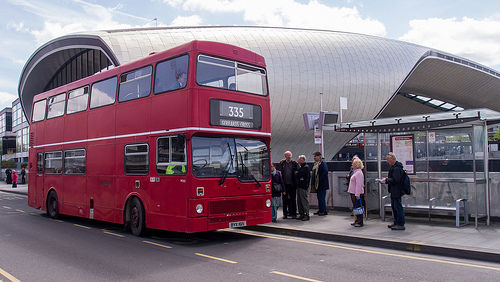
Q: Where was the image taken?
A: It was taken at the road.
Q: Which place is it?
A: It is a road.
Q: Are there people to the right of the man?
A: No, the person is to the left of the man.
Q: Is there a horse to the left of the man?
A: No, there is a person to the left of the man.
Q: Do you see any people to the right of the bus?
A: Yes, there is a person to the right of the bus.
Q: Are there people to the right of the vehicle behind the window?
A: Yes, there is a person to the right of the bus.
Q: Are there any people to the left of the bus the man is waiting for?
A: No, the person is to the right of the bus.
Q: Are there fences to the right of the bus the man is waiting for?
A: No, there is a person to the right of the bus.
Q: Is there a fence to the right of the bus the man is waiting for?
A: No, there is a person to the right of the bus.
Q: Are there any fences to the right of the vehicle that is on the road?
A: No, there is a person to the right of the bus.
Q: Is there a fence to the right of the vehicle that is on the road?
A: No, there is a person to the right of the bus.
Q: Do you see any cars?
A: No, there are no cars.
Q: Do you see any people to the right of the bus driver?
A: Yes, there is a person to the right of the bus driver.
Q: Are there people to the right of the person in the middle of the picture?
A: Yes, there is a person to the right of the bus driver.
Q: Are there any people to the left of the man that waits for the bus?
A: Yes, there is a person to the left of the man.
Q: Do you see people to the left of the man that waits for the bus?
A: Yes, there is a person to the left of the man.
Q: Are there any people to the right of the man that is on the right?
A: No, the person is to the left of the man.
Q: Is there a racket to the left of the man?
A: No, there is a person to the left of the man.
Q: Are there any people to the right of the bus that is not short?
A: Yes, there is a person to the right of the bus.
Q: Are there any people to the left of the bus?
A: No, the person is to the right of the bus.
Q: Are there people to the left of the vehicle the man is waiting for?
A: No, the person is to the right of the bus.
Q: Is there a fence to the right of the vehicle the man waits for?
A: No, there is a person to the right of the bus.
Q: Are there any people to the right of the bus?
A: Yes, there is a person to the right of the bus.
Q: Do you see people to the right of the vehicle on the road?
A: Yes, there is a person to the right of the bus.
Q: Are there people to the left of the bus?
A: No, the person is to the right of the bus.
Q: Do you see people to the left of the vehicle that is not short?
A: No, the person is to the right of the bus.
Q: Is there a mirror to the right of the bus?
A: No, there is a person to the right of the bus.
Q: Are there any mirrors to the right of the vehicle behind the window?
A: No, there is a person to the right of the bus.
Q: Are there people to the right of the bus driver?
A: Yes, there is a person to the right of the bus driver.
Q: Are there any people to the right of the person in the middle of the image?
A: Yes, there is a person to the right of the bus driver.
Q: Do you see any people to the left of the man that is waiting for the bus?
A: Yes, there is a person to the left of the man.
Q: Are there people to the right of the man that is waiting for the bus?
A: No, the person is to the left of the man.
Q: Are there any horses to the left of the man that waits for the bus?
A: No, there is a person to the left of the man.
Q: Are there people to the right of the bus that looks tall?
A: Yes, there is a person to the right of the bus.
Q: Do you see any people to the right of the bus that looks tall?
A: Yes, there is a person to the right of the bus.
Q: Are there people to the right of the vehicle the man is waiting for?
A: Yes, there is a person to the right of the bus.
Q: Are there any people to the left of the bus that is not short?
A: No, the person is to the right of the bus.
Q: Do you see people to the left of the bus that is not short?
A: No, the person is to the right of the bus.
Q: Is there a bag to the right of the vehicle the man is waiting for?
A: No, there is a person to the right of the bus.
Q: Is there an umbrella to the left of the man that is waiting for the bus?
A: No, there is a person to the left of the man.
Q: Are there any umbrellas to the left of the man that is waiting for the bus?
A: No, there is a person to the left of the man.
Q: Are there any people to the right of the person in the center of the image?
A: Yes, there is a person to the right of the bus driver.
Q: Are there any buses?
A: Yes, there is a bus.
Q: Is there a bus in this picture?
A: Yes, there is a bus.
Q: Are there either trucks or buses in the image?
A: Yes, there is a bus.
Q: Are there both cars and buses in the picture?
A: No, there is a bus but no cars.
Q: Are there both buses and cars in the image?
A: No, there is a bus but no cars.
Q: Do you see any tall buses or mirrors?
A: Yes, there is a tall bus.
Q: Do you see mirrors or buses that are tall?
A: Yes, the bus is tall.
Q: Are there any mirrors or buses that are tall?
A: Yes, the bus is tall.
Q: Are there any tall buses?
A: Yes, there is a tall bus.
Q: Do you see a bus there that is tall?
A: Yes, there is a bus that is tall.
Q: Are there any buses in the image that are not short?
A: Yes, there is a tall bus.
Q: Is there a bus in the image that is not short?
A: Yes, there is a tall bus.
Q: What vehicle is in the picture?
A: The vehicle is a bus.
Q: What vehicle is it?
A: The vehicle is a bus.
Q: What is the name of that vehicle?
A: That is a bus.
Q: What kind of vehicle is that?
A: That is a bus.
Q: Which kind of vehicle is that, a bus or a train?
A: That is a bus.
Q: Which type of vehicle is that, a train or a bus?
A: That is a bus.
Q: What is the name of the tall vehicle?
A: The vehicle is a bus.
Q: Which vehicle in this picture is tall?
A: The vehicle is a bus.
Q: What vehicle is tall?
A: The vehicle is a bus.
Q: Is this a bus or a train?
A: This is a bus.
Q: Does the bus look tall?
A: Yes, the bus is tall.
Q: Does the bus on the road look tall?
A: Yes, the bus is tall.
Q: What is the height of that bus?
A: The bus is tall.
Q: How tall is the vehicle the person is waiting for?
A: The bus is tall.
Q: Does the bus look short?
A: No, the bus is tall.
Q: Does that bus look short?
A: No, the bus is tall.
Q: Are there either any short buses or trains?
A: No, there is a bus but it is tall.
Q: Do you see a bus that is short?
A: No, there is a bus but it is tall.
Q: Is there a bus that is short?
A: No, there is a bus but it is tall.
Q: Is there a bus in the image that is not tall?
A: No, there is a bus but it is tall.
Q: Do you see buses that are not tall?
A: No, there is a bus but it is tall.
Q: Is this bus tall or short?
A: The bus is tall.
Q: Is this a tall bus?
A: Yes, this is a tall bus.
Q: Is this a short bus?
A: No, this is a tall bus.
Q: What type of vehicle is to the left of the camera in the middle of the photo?
A: The vehicle is a bus.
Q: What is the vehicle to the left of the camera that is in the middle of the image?
A: The vehicle is a bus.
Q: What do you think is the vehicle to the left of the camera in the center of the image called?
A: The vehicle is a bus.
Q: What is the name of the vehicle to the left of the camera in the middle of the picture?
A: The vehicle is a bus.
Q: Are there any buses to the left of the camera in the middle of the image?
A: Yes, there is a bus to the left of the camera.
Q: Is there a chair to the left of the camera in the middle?
A: No, there is a bus to the left of the camera.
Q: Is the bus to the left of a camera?
A: Yes, the bus is to the left of a camera.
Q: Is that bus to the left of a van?
A: No, the bus is to the left of a camera.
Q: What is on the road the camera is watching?
A: The bus is on the road.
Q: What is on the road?
A: The bus is on the road.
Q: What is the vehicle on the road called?
A: The vehicle is a bus.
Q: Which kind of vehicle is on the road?
A: The vehicle is a bus.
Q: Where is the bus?
A: The bus is on the road.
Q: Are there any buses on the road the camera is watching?
A: Yes, there is a bus on the road.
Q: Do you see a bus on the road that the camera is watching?
A: Yes, there is a bus on the road.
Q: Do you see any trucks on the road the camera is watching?
A: No, there is a bus on the road.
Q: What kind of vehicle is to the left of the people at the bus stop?
A: The vehicle is a bus.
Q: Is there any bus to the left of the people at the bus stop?
A: Yes, there is a bus to the left of the people.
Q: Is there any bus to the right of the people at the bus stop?
A: No, the bus is to the left of the people.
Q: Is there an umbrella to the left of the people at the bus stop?
A: No, there is a bus to the left of the people.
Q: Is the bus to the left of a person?
A: Yes, the bus is to the left of a person.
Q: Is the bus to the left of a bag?
A: No, the bus is to the left of a person.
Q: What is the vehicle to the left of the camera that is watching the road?
A: The vehicle is a bus.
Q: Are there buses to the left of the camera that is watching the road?
A: Yes, there is a bus to the left of the camera.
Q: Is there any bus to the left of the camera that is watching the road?
A: Yes, there is a bus to the left of the camera.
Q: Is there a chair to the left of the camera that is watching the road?
A: No, there is a bus to the left of the camera.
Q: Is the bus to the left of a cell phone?
A: No, the bus is to the left of a camera.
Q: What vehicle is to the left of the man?
A: The vehicle is a bus.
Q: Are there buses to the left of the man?
A: Yes, there is a bus to the left of the man.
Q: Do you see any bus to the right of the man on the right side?
A: No, the bus is to the left of the man.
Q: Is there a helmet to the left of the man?
A: No, there is a bus to the left of the man.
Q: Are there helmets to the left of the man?
A: No, there is a bus to the left of the man.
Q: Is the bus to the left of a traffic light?
A: No, the bus is to the left of a man.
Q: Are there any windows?
A: Yes, there is a window.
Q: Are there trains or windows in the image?
A: Yes, there is a window.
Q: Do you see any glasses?
A: No, there are no glasses.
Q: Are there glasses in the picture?
A: No, there are no glasses.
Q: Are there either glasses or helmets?
A: No, there are no glasses or helmets.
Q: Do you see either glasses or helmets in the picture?
A: No, there are no glasses or helmets.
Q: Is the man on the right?
A: Yes, the man is on the right of the image.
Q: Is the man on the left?
A: No, the man is on the right of the image.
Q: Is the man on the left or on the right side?
A: The man is on the right of the image.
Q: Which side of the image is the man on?
A: The man is on the right of the image.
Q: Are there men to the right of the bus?
A: Yes, there is a man to the right of the bus.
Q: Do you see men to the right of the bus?
A: Yes, there is a man to the right of the bus.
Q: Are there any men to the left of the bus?
A: No, the man is to the right of the bus.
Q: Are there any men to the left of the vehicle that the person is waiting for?
A: No, the man is to the right of the bus.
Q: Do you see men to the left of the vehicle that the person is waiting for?
A: No, the man is to the right of the bus.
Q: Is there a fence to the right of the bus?
A: No, there is a man to the right of the bus.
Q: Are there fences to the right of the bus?
A: No, there is a man to the right of the bus.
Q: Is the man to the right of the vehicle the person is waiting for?
A: Yes, the man is to the right of the bus.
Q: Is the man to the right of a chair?
A: No, the man is to the right of the bus.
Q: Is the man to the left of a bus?
A: No, the man is to the right of a bus.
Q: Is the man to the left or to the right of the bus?
A: The man is to the right of the bus.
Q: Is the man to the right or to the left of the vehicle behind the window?
A: The man is to the right of the bus.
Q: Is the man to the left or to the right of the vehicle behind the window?
A: The man is to the right of the bus.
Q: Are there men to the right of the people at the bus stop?
A: Yes, there is a man to the right of the people.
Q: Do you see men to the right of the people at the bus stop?
A: Yes, there is a man to the right of the people.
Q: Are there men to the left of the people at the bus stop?
A: No, the man is to the right of the people.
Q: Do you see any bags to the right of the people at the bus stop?
A: No, there is a man to the right of the people.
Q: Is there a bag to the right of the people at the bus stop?
A: No, there is a man to the right of the people.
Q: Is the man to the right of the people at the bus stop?
A: Yes, the man is to the right of the people.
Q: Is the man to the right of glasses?
A: No, the man is to the right of the people.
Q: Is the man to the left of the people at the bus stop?
A: No, the man is to the right of the people.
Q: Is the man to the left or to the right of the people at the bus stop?
A: The man is to the right of the people.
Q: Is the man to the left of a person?
A: No, the man is to the right of a person.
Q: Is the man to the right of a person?
A: Yes, the man is to the right of a person.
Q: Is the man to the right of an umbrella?
A: No, the man is to the right of a person.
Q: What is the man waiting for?
A: The man is waiting for the bus.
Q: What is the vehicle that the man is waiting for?
A: The vehicle is a bus.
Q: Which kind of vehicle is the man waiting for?
A: The man is waiting for the bus.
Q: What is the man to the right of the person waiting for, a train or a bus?
A: The man is waiting for a bus.